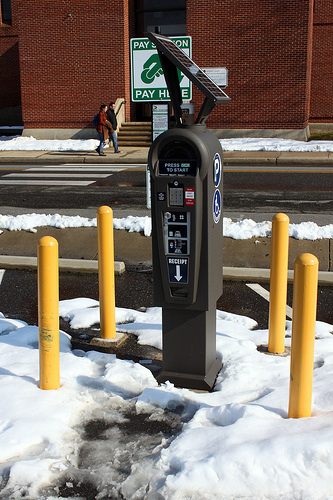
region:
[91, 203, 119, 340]
The pole is yellow in color.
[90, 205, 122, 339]
The pole is made of steel.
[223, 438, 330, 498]
Snow is in the forefront.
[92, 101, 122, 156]
Two people are walking on the sidewalk.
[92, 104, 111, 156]
The woman is carrying a coat.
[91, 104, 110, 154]
The woman is carrying a back pack.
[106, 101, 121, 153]
The man is wearing blue jeans.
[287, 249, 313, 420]
pole near a street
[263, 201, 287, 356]
pole near a street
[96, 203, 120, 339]
pole near a street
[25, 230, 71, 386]
pole near a street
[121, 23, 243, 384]
parking meter near street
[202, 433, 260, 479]
snow on side walk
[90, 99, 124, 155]
woman and man on side walk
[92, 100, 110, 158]
woman holding a back pack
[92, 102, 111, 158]
woman wearing blue jeans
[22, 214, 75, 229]
snow near a street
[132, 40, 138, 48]
white letter on sign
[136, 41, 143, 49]
white letter on sign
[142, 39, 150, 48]
white letter on sign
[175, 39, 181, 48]
white letter on sign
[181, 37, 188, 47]
white letter on sign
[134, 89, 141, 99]
white letter on sign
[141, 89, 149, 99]
white letter on sign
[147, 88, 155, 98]
white letter on sign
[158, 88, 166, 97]
white letter on sign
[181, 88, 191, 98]
white letter on sign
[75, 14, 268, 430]
this is a parking meter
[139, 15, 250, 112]
solar panel on meter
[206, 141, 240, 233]
blue signs on meter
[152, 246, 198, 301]
arrow on parking meter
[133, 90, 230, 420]
parking meter is grey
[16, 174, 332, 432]
poles surround parking meter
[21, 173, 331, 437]
the poles are yellow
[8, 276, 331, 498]
snow on the ground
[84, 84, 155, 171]
people walking together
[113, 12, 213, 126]
green and white sign in background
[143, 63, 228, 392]
Snowy sidewalk parking meter.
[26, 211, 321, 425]
Yellow poles surround parking meter.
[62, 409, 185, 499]
Footprints in slushy snow.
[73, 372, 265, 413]
Shadow from yellow pole.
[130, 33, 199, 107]
Green and white sign 'pay here'.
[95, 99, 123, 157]
Man and women walking sidewalk.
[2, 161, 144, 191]
White pedestrian crossing lines.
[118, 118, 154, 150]
Group stairs leading into building.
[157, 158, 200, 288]
Complete instructions use of meter.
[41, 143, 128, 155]
Shadows behind couple walking.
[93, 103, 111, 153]
woman on the sidewalk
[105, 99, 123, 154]
man walking on the sidewalk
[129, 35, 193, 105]
green and white sign